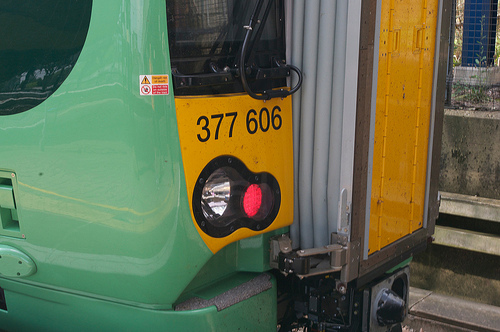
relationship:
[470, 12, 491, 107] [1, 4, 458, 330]
plant behind train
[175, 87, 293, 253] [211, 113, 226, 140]
yellow panel has number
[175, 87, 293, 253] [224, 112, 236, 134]
yellow panel has number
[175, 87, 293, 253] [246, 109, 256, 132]
yellow panel has number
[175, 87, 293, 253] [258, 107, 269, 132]
yellow panel has number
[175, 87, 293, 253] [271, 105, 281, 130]
yellow panel has number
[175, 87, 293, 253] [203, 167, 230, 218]
yellow panel has lights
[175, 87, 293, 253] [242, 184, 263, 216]
yellow panel has lights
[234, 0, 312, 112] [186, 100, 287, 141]
hose above number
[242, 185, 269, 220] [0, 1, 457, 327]
light on bus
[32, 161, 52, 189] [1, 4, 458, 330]
speck on train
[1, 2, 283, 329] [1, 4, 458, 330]
panel of train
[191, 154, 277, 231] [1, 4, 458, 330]
headlights on train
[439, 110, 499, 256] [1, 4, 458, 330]
concrete wall behind train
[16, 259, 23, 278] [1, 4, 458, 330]
bolts on train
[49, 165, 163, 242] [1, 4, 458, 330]
reflection on train